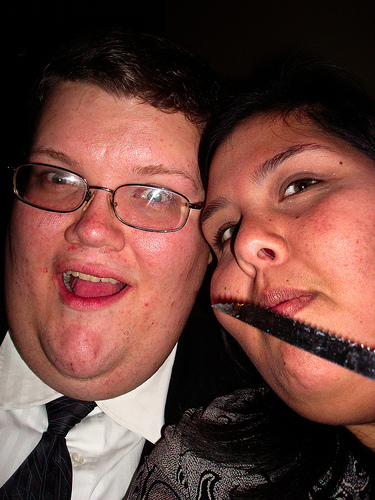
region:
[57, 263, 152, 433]
a man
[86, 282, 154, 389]
a man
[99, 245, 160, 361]
a man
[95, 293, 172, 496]
a man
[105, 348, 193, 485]
a man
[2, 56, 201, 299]
Man with brown hair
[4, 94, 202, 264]
Man wearing glasses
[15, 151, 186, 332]
A smiling man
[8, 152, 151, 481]
A man wearing a white shirt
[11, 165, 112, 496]
A man wearing a black tie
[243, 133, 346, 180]
A woman's eyebrow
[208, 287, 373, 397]
A dirty knife blade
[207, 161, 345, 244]
A woman's brown eyes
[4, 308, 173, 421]
A man's double chin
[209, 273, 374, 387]
A serrated knife blade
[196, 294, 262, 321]
edge of black knife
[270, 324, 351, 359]
spots on black knife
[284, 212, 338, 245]
freckles on woman's face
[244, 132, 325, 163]
woman's bushy eye brow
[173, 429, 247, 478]
end of woman's long black hair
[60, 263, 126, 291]
brown teeth in man's mouth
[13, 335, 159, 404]
deposit of fat under chin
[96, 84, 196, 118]
edge of black hair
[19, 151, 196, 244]
wire rimmed eye glasses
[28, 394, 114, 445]
knot in black tie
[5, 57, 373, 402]
Two people in the foreground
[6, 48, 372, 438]
A man and a woman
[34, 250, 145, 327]
The Man is smiling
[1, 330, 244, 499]
Man is wearing a suit and tie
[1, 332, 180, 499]
Dress shirt is white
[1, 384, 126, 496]
The tie is black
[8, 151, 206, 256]
Man is wearing glasses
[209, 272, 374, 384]
A knife is in front of the woman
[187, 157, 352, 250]
Woman has brown colored eyes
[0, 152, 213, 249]
Man's eyeglasses have a thin frame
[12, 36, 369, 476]
two faces posing for camera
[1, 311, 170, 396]
a double chin here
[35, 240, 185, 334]
acne on face here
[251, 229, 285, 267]
a big nostril here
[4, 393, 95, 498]
a black tie here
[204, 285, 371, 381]
part of a knife here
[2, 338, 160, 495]
a white shirt here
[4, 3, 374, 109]
black in the background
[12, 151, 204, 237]
glasses on face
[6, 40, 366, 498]
two people here